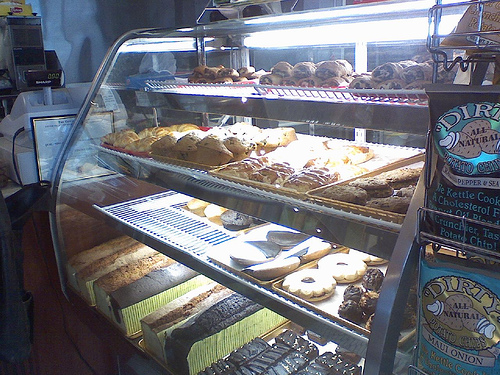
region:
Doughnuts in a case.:
[283, 256, 348, 301]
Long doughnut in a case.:
[245, 249, 293, 279]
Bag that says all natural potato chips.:
[415, 281, 495, 363]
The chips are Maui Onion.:
[416, 325, 498, 372]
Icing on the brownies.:
[242, 340, 319, 373]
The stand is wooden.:
[4, 195, 51, 349]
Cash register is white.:
[9, 74, 124, 116]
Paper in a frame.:
[28, 109, 131, 185]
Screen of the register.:
[18, 65, 69, 90]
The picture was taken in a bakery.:
[6, 6, 499, 363]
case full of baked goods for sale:
[55, 23, 466, 345]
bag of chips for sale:
[413, 254, 488, 370]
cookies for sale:
[277, 253, 344, 303]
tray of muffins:
[147, 120, 284, 152]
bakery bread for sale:
[62, 241, 169, 354]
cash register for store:
[2, 80, 137, 185]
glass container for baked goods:
[46, 14, 131, 342]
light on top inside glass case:
[124, 11, 424, 77]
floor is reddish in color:
[45, 326, 77, 359]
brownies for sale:
[218, 328, 323, 364]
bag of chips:
[399, 241, 497, 367]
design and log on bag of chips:
[412, 260, 498, 348]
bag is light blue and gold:
[411, 251, 498, 373]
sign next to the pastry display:
[13, 108, 133, 182]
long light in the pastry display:
[236, 17, 471, 55]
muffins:
[139, 108, 293, 185]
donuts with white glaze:
[284, 232, 359, 313]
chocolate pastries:
[344, 256, 398, 341]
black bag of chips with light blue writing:
[423, 89, 495, 264]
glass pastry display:
[36, 23, 427, 374]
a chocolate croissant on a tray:
[271, 61, 291, 78]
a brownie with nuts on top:
[276, 327, 322, 357]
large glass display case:
[50, 0, 499, 372]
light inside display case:
[239, 14, 457, 46]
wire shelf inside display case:
[146, 77, 431, 105]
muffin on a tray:
[196, 133, 233, 165]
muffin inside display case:
[153, 134, 178, 157]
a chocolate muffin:
[220, 209, 250, 231]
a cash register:
[1, 65, 134, 182]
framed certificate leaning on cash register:
[28, 107, 120, 185]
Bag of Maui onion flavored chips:
[418, 254, 498, 374]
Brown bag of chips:
[425, 76, 498, 262]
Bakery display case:
[50, 19, 423, 371]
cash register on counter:
[6, 62, 126, 184]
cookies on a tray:
[319, 166, 420, 216]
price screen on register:
[24, 69, 65, 86]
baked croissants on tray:
[100, 129, 153, 154]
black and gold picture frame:
[29, 110, 120, 183]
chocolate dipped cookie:
[234, 234, 280, 264]